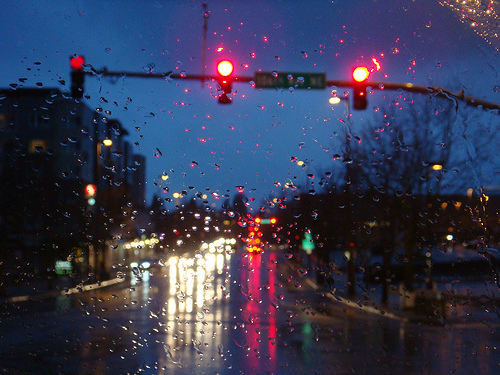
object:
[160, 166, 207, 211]
rain drop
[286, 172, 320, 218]
rain drop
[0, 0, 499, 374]
wind shield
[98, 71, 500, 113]
pole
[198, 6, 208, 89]
traffic camera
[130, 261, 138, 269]
headlights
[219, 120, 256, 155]
clouds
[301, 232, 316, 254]
sign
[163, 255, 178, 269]
lights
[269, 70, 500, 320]
trees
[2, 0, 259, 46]
raindrops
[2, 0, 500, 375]
glass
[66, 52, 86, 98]
traffic light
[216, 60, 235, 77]
red light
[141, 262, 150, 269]
light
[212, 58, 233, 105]
light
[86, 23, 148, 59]
clouds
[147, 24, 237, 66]
clouds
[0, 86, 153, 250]
building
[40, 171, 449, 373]
street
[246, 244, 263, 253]
cars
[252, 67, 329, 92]
sign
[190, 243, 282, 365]
road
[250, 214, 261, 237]
stop light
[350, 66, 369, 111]
light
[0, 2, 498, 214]
sky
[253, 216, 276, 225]
lights